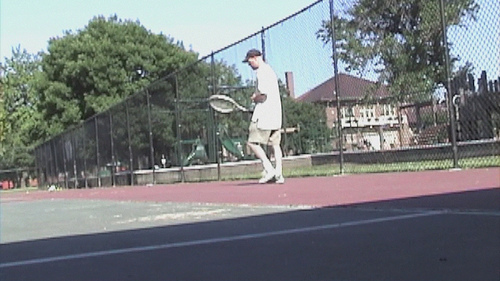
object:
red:
[311, 173, 409, 199]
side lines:
[0, 189, 500, 218]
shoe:
[275, 175, 285, 185]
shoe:
[258, 168, 279, 184]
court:
[0, 162, 500, 280]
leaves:
[0, 0, 498, 180]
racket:
[208, 95, 256, 114]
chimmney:
[284, 70, 295, 98]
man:
[240, 49, 296, 185]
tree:
[313, 1, 498, 144]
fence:
[32, 0, 500, 190]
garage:
[381, 127, 439, 151]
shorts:
[247, 121, 282, 145]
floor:
[0, 163, 500, 280]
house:
[285, 71, 443, 149]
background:
[0, 0, 498, 178]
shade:
[0, 185, 499, 280]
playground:
[43, 111, 500, 189]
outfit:
[248, 64, 282, 146]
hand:
[251, 93, 262, 103]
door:
[381, 127, 401, 148]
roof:
[291, 72, 408, 101]